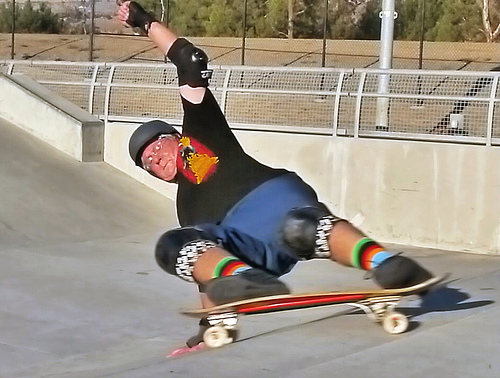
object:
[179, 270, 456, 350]
board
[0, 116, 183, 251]
ramp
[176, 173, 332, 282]
shorts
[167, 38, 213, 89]
pad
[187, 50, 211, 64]
elbow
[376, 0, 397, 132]
pole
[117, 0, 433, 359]
man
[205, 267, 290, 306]
shoe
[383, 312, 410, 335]
wheel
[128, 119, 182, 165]
helmet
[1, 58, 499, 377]
park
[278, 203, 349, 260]
pad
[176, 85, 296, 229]
shirt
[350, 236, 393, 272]
sock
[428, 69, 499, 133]
shadow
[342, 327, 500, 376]
ground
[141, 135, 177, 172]
glasses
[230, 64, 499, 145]
fence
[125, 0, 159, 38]
guard